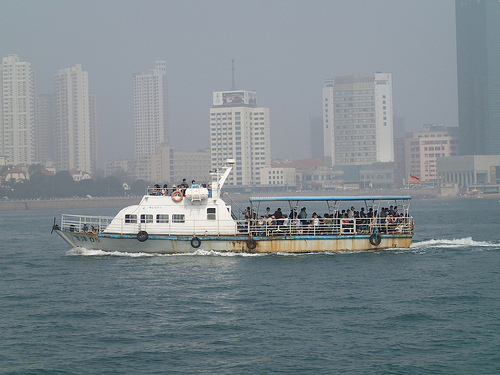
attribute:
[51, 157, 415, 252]
boat — white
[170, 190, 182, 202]
floatation ring — orange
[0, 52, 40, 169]
building — tall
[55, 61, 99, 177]
building — tall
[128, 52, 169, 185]
building — tall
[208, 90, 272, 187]
building — tall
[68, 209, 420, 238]
railings — white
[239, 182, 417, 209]
roof — blue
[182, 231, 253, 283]
object — black, round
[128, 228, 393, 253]
rings — black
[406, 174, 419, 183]
flag — flying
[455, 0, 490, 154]
black building — tall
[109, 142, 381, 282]
boat — red, round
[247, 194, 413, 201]
shelter — blue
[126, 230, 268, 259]
floats — Black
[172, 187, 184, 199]
float — red, life-saving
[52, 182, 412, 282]
boat — white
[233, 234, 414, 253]
bottom — dirty